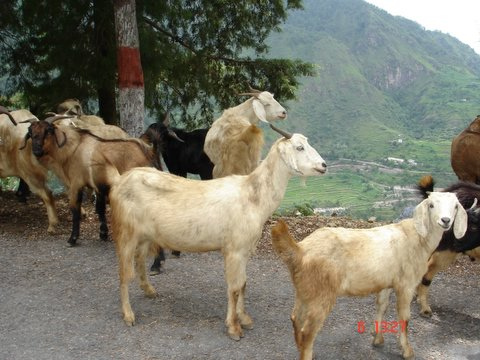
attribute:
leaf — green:
[203, 6, 229, 33]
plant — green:
[138, 9, 283, 121]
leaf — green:
[273, 62, 299, 79]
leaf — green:
[243, 54, 265, 81]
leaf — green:
[138, 75, 162, 92]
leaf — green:
[38, 30, 64, 60]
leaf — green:
[155, 97, 176, 133]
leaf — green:
[52, 43, 84, 62]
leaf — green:
[152, 36, 178, 63]